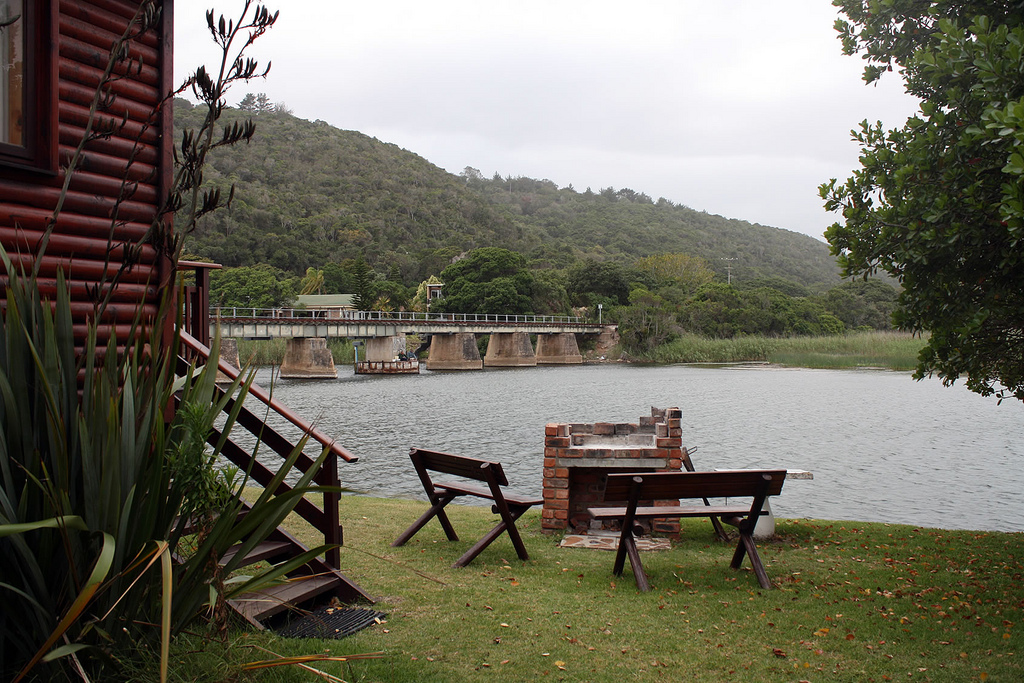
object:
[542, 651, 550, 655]
leaves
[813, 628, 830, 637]
leaves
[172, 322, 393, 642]
stairs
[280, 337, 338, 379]
bridges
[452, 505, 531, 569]
legs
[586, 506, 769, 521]
seat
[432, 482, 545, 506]
seat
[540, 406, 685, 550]
brick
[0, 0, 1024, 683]
outdoors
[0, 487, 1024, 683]
ground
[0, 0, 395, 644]
building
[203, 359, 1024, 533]
lake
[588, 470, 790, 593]
bench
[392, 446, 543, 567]
bench